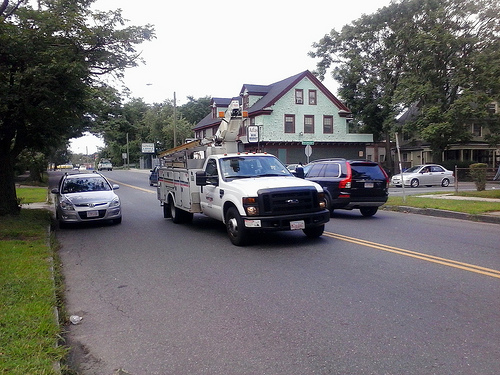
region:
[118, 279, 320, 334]
Gray asphalt street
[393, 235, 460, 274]
double yellow line on the street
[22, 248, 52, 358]
Short green grass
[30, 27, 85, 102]
Green tree leaves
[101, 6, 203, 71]
Tree branches with white sky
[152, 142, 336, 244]
a white utility truck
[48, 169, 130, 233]
The front of a silver car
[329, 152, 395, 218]
THe back of a black SUV with red rear lights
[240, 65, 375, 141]
A building with 5 windows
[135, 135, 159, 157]
A sign in the background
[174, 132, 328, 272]
a white tow truck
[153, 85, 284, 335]
a white tow truck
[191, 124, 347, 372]
a white tow truck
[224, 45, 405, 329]
a white tow truck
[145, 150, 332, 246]
truck driving on road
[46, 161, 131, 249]
silver car on side of road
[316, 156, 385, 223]
black suv on road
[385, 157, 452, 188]
silver car on side of road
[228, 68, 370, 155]
house on corner lot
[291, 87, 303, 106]
window on side of house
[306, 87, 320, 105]
window on side of house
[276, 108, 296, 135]
window on side of house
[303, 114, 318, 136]
window on side of house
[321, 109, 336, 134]
window on side of house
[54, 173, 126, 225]
Silver Honda parked on the left.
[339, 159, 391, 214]
Rearend of an black SUV.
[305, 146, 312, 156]
Rear view of a stop sign.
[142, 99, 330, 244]
White truck with lift.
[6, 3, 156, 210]
Tall tree along roadside.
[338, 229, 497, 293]
Yellow double lines on street.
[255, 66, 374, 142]
Side second story view of a light green house.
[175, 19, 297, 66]
White and hazy skies.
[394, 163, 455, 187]
Silver small sedan at intersection.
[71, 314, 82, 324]
White tissue crumbled on the ground.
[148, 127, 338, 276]
the truck has utility boxes on it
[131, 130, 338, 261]
the truck is white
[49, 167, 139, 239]
this car is silver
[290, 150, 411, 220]
this car is black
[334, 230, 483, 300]
a double yellow line is down the street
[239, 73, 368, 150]
the house is painted light green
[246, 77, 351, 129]
the roof & trim is brown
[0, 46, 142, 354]
the street is tree lined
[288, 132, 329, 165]
a stop sign is on the corner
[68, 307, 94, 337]
a piece of trash in the gutter